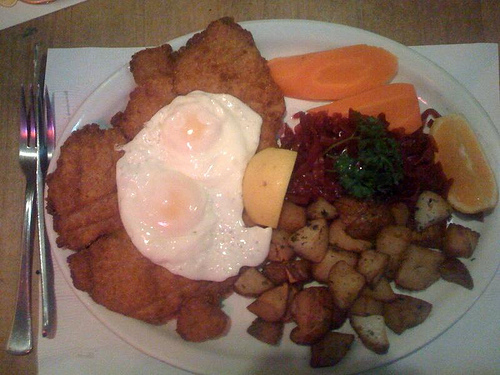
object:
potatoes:
[396, 246, 447, 290]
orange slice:
[424, 112, 499, 218]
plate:
[47, 17, 499, 372]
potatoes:
[290, 219, 331, 262]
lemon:
[239, 147, 302, 229]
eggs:
[112, 88, 276, 281]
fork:
[4, 67, 57, 355]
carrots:
[268, 40, 397, 103]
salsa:
[287, 117, 440, 200]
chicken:
[289, 281, 339, 347]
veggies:
[269, 40, 435, 207]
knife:
[30, 41, 66, 341]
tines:
[16, 82, 56, 174]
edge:
[431, 290, 490, 355]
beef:
[75, 228, 237, 340]